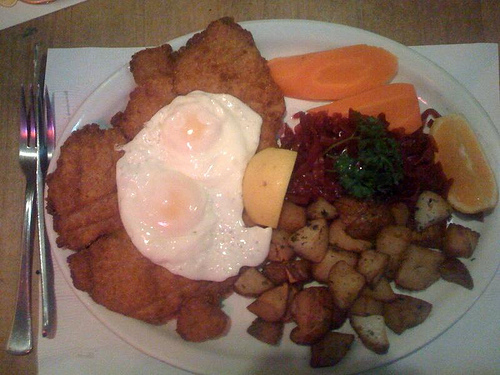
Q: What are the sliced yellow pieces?
A: Lemons.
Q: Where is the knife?
A: On top of the fork.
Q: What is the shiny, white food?
A: Eggs.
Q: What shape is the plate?
A: Oblong.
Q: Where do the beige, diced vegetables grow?
A: Underground.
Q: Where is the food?
A: On a plate.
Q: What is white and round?
A: Plate.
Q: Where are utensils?
A: To the left of the plate.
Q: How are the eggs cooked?
A: Over easy.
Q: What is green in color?
A: Paisley.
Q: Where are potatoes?
A: On the plate.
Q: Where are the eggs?
A: On the meat.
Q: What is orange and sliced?
A: Fruit.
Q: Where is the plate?
A: On the table.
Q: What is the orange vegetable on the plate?
A: Carrot.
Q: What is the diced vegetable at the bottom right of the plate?
A: Potatoes.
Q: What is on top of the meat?
A: Eggs.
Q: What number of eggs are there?
A: Two.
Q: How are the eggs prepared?
A: Over easy.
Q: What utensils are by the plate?
A: Knife and fork.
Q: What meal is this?
A: Breakfast.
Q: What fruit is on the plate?
A: Orange.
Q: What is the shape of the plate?
A: Round.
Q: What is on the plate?
A: Food.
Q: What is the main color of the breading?
A: Brown.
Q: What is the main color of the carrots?
A: Orange.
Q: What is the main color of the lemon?
A: Yellow.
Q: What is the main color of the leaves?
A: Green.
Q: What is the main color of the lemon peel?
A: Yellow.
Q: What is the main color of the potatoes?
A: Brown.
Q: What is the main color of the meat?
A: Brown.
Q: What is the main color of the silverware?
A: Silver.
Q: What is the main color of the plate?
A: White.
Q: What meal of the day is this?
A: Breakfast.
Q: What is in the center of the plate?
A: Lemon wedge.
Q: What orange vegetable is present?
A: Carrot.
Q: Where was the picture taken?
A: In a room.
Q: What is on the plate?
A: Food.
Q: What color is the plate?
A: White.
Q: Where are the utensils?
A: On the left of the plate.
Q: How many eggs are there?
A: Two.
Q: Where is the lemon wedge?
A: The center of the plate.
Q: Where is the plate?
A: On a table top.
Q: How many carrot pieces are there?
A: Two.